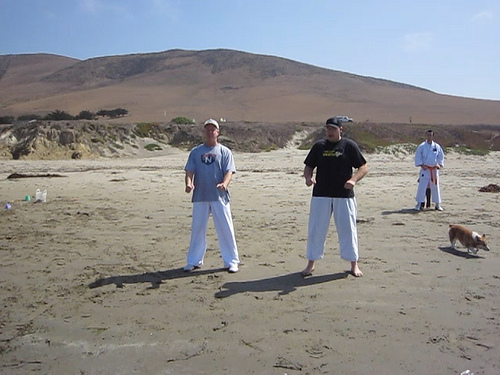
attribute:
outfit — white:
[411, 142, 449, 217]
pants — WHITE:
[295, 189, 372, 290]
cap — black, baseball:
[321, 113, 347, 130]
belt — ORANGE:
[417, 159, 442, 176]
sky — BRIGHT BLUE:
[0, 0, 499, 100]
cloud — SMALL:
[403, 29, 439, 49]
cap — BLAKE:
[316, 112, 355, 131]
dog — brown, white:
[445, 220, 493, 264]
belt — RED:
[417, 157, 437, 180]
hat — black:
[317, 110, 349, 132]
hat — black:
[323, 115, 342, 130]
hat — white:
[196, 117, 230, 129]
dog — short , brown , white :
[441, 214, 496, 269]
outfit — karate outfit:
[405, 142, 445, 204]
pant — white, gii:
[168, 194, 256, 266]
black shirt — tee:
[300, 138, 367, 198]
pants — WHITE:
[184, 190, 239, 270]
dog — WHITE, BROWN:
[442, 223, 492, 255]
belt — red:
[415, 160, 442, 185]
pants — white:
[148, 187, 265, 258]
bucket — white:
[34, 184, 48, 204]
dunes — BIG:
[28, 121, 175, 167]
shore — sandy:
[5, 160, 451, 365]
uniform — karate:
[410, 139, 446, 208]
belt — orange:
[417, 160, 438, 182]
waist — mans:
[413, 161, 439, 171]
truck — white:
[335, 113, 353, 121]